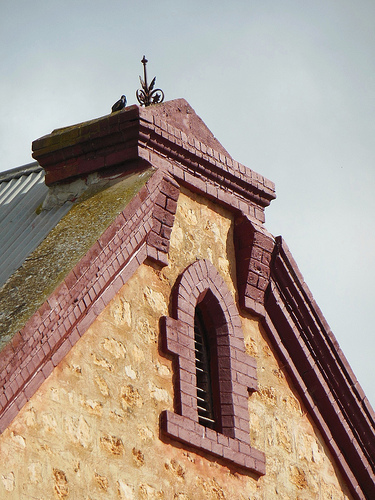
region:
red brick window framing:
[157, 405, 202, 448]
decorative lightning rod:
[122, 41, 169, 113]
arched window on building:
[107, 231, 284, 475]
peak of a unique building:
[4, 52, 360, 499]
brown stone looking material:
[67, 368, 146, 414]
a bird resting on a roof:
[34, 59, 178, 140]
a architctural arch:
[154, 246, 270, 482]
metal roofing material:
[6, 185, 57, 238]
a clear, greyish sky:
[235, 25, 342, 100]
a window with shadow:
[151, 259, 298, 469]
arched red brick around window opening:
[158, 251, 273, 480]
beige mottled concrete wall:
[51, 380, 149, 486]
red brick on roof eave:
[261, 232, 370, 495]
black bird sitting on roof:
[110, 91, 131, 114]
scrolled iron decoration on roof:
[135, 51, 169, 109]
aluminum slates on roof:
[5, 169, 45, 283]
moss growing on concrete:
[5, 171, 143, 279]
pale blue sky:
[244, 49, 342, 185]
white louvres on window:
[192, 324, 217, 430]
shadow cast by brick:
[222, 221, 255, 314]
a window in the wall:
[163, 257, 265, 477]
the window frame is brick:
[159, 249, 271, 475]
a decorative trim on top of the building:
[110, 43, 171, 124]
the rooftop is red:
[37, 95, 277, 228]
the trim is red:
[6, 113, 371, 459]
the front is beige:
[7, 189, 341, 494]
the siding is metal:
[2, 151, 100, 286]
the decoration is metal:
[136, 54, 171, 107]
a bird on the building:
[106, 86, 132, 114]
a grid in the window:
[188, 298, 219, 431]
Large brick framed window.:
[159, 258, 269, 481]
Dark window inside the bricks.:
[189, 304, 225, 434]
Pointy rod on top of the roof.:
[138, 54, 150, 85]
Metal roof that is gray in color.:
[1, 162, 85, 285]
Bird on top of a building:
[110, 92, 126, 112]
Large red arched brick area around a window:
[161, 246, 270, 478]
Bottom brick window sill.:
[160, 410, 267, 478]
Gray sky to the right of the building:
[277, 118, 374, 231]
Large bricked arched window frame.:
[162, 256, 267, 477]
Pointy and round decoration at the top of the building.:
[134, 53, 165, 104]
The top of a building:
[16, 77, 361, 499]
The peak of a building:
[11, 65, 371, 497]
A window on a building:
[158, 246, 284, 485]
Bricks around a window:
[168, 259, 271, 484]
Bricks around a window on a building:
[155, 253, 277, 468]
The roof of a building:
[4, 140, 131, 291]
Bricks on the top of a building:
[34, 54, 315, 202]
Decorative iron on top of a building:
[128, 54, 173, 109]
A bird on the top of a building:
[105, 88, 132, 116]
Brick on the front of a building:
[137, 137, 299, 304]